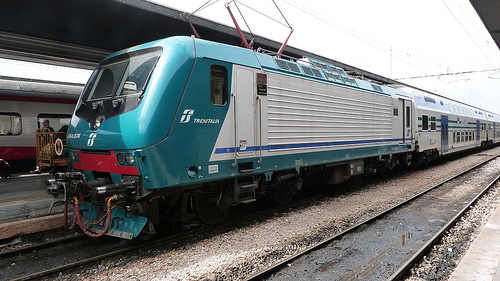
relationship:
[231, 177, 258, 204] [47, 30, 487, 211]
steps on side of train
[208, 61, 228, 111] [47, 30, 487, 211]
window on train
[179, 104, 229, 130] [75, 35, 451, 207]
logo on train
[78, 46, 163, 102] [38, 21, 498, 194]
window on train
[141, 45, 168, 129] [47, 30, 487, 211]
light on train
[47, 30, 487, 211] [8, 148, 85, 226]
train at platform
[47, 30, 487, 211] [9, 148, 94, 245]
train at platform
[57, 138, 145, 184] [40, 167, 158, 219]
trim front of bumper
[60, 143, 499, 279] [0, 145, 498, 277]
rocks on ground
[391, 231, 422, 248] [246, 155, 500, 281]
puddle between train track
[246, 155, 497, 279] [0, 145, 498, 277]
train track on ground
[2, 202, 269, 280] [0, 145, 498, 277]
train track on ground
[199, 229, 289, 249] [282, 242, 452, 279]
gravel beside tracks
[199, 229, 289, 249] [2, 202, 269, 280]
gravel beside train track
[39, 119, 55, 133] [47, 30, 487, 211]
man on train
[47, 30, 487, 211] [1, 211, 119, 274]
train on track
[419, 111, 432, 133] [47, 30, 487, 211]
window on train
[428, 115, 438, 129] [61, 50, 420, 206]
window on train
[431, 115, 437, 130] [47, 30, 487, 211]
window on train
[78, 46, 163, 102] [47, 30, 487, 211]
window on train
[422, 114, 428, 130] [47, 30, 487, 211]
window on train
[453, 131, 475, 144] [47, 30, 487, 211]
windows on train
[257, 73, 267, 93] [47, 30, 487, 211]
window on train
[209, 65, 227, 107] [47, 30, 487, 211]
window on train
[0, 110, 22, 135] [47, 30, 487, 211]
window on train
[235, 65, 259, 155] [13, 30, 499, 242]
door on train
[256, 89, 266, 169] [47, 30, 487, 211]
rail on train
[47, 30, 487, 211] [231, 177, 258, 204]
train has steps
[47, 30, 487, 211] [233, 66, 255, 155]
train has door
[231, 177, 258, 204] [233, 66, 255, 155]
steps lead to door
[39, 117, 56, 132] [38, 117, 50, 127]
man has a head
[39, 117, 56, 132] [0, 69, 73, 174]
man on platform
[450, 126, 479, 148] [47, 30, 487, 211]
windows on train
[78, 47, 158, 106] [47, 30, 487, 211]
window on train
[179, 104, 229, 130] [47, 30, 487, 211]
logo on train